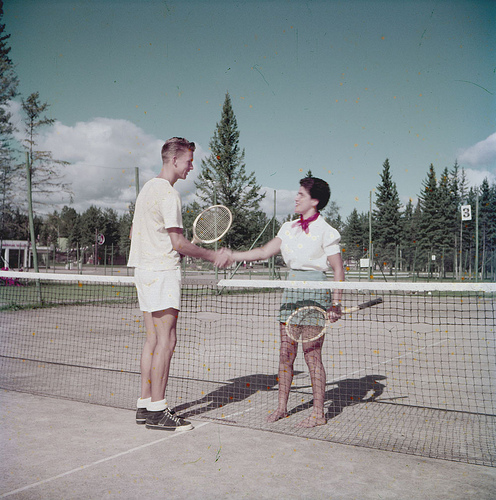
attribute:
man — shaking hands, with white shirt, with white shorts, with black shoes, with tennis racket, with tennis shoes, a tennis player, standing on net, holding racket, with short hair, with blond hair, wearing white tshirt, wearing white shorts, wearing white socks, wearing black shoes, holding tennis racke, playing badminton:
[111, 133, 228, 439]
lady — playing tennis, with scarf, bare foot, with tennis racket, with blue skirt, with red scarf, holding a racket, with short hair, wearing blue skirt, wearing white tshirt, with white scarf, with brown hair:
[231, 171, 350, 431]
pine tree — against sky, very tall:
[374, 161, 420, 273]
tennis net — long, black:
[2, 283, 493, 463]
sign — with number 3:
[458, 204, 472, 221]